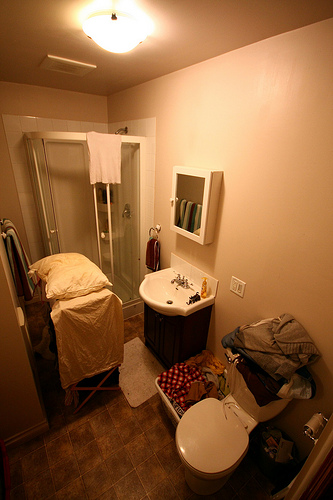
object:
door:
[32, 139, 140, 302]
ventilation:
[38, 55, 96, 78]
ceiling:
[0, 0, 331, 98]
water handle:
[122, 209, 128, 218]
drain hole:
[167, 300, 172, 304]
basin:
[139, 267, 214, 317]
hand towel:
[145, 239, 159, 272]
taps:
[170, 273, 190, 289]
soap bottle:
[201, 277, 208, 299]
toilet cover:
[177, 397, 250, 474]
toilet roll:
[302, 413, 325, 437]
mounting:
[302, 411, 331, 443]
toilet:
[175, 348, 294, 495]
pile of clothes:
[221, 312, 321, 408]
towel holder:
[149, 224, 162, 239]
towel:
[1, 217, 35, 301]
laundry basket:
[154, 349, 228, 426]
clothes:
[158, 351, 225, 421]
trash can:
[259, 428, 295, 484]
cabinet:
[142, 303, 213, 371]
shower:
[23, 130, 148, 321]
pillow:
[29, 252, 114, 299]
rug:
[118, 336, 166, 409]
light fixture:
[79, 14, 153, 56]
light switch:
[230, 276, 247, 298]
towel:
[86, 131, 122, 186]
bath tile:
[24, 132, 147, 323]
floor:
[0, 310, 278, 500]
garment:
[185, 348, 226, 376]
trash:
[261, 427, 294, 462]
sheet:
[50, 287, 124, 391]